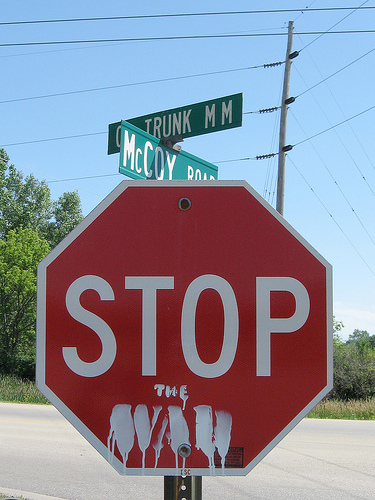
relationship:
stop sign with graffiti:
[37, 180, 332, 478] [108, 381, 230, 473]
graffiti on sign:
[108, 381, 233, 473] [16, 169, 346, 481]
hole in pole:
[177, 482, 189, 491] [162, 474, 202, 498]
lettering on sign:
[139, 109, 192, 138] [105, 89, 246, 159]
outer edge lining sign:
[35, 178, 333, 476] [36, 180, 334, 477]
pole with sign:
[162, 474, 202, 498] [36, 180, 334, 477]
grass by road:
[1, 371, 361, 405] [4, 405, 349, 497]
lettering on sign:
[63, 273, 309, 377] [36, 180, 334, 477]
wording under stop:
[108, 384, 233, 459] [60, 274, 310, 376]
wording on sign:
[108, 384, 233, 459] [36, 180, 334, 477]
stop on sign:
[60, 274, 310, 376] [36, 180, 334, 477]